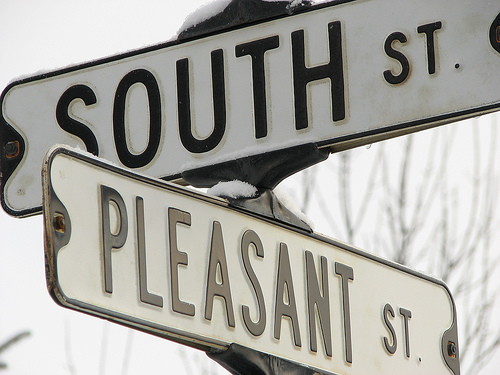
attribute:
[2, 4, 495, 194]
sign — black, white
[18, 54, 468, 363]
street sign —  Black and white,  pole's, of street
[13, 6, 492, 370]
black/white sign — of street,  Black and white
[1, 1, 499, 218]
street sign — white, black, black and white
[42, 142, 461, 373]
street sign —  pole's,  Black and white,  street's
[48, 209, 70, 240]
screw —  small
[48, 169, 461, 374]
sign — white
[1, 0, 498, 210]
sign — white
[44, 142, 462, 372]
sign —  South st, of board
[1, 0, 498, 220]
sign board — standard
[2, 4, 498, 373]
wall — big